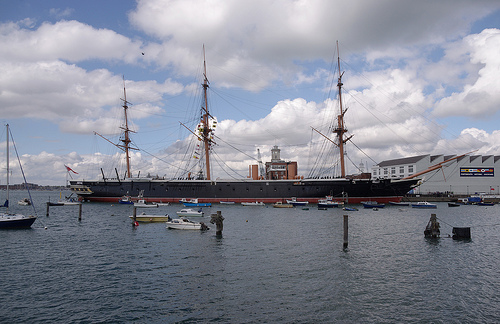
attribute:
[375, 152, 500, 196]
building — white, large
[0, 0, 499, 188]
sky — bright, blue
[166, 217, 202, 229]
boat — docked, small, large, white, small`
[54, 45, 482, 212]
ship — antique, docked, black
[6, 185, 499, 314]
water — blue